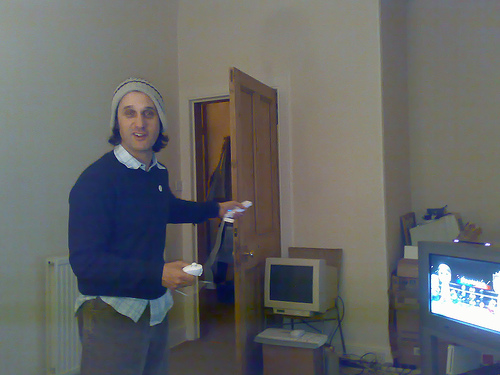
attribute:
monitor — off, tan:
[262, 252, 342, 323]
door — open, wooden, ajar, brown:
[221, 62, 282, 374]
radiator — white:
[40, 251, 88, 374]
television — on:
[415, 237, 499, 357]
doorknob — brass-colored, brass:
[240, 249, 256, 264]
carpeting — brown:
[157, 289, 271, 374]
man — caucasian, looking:
[57, 71, 245, 374]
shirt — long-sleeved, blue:
[59, 149, 220, 302]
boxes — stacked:
[387, 245, 453, 369]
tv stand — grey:
[420, 325, 499, 373]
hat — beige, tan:
[104, 78, 178, 138]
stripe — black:
[112, 81, 162, 99]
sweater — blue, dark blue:
[60, 151, 220, 298]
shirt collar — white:
[107, 142, 166, 176]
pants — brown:
[70, 290, 171, 374]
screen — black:
[269, 265, 315, 305]